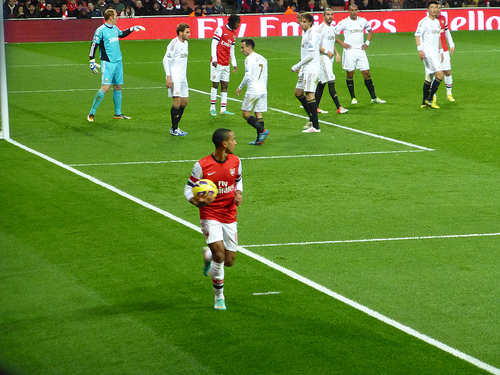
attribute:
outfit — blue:
[86, 24, 132, 119]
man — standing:
[182, 129, 244, 312]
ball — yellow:
[193, 179, 220, 204]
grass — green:
[0, 30, 498, 374]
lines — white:
[246, 232, 498, 250]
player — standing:
[162, 22, 193, 135]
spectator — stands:
[42, 3, 58, 15]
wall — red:
[106, 9, 499, 39]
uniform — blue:
[86, 10, 145, 124]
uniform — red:
[211, 27, 238, 69]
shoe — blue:
[168, 128, 187, 136]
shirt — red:
[186, 155, 242, 223]